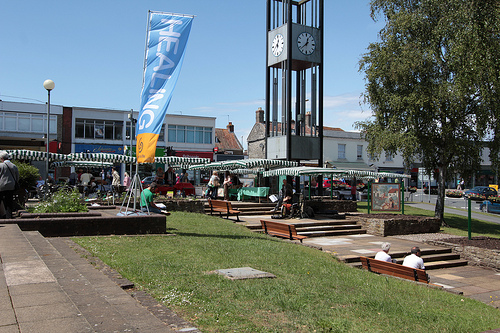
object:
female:
[374, 242, 395, 263]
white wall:
[325, 134, 363, 163]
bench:
[259, 219, 307, 243]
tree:
[352, 6, 500, 222]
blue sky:
[2, 0, 384, 134]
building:
[317, 129, 493, 169]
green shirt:
[141, 188, 154, 206]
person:
[139, 182, 171, 216]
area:
[79, 210, 499, 331]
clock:
[270, 33, 285, 57]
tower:
[265, 0, 322, 165]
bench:
[207, 198, 243, 222]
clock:
[296, 31, 317, 56]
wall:
[244, 121, 268, 159]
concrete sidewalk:
[336, 234, 406, 253]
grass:
[190, 258, 235, 273]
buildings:
[0, 97, 67, 143]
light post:
[43, 77, 54, 177]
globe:
[43, 79, 55, 90]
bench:
[361, 254, 444, 287]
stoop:
[16, 205, 166, 236]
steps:
[243, 219, 369, 238]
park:
[1, 99, 499, 331]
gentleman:
[402, 245, 425, 269]